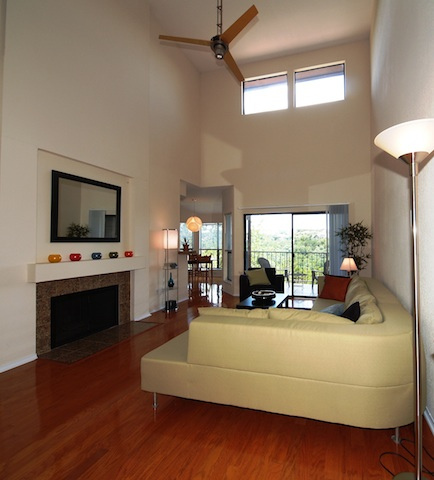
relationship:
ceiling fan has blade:
[158, 1, 259, 84] [222, 3, 258, 45]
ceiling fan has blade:
[158, 1, 259, 84] [158, 34, 214, 48]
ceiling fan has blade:
[158, 1, 259, 84] [223, 47, 246, 84]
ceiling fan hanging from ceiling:
[158, 1, 259, 84] [154, 1, 376, 74]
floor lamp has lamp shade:
[375, 115, 433, 479] [372, 116, 433, 169]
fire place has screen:
[35, 269, 131, 357] [52, 284, 120, 346]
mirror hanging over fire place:
[49, 166, 122, 245] [35, 269, 131, 357]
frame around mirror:
[50, 168, 122, 244] [49, 166, 122, 245]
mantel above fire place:
[26, 253, 145, 283] [35, 269, 131, 357]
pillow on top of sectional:
[318, 273, 351, 303] [139, 275, 427, 446]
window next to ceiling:
[292, 59, 347, 110] [154, 1, 376, 74]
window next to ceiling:
[236, 71, 288, 118] [154, 1, 376, 74]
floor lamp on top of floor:
[375, 115, 433, 479] [1, 296, 432, 479]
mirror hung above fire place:
[49, 166, 122, 245] [35, 269, 131, 357]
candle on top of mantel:
[48, 252, 62, 264] [26, 253, 145, 283]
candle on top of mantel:
[69, 253, 82, 262] [26, 253, 145, 283]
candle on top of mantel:
[91, 250, 103, 261] [26, 253, 145, 283]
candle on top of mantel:
[108, 250, 119, 259] [26, 253, 145, 283]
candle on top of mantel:
[123, 249, 134, 260] [26, 253, 145, 283]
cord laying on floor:
[378, 435, 433, 478] [1, 296, 432, 479]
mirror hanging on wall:
[49, 166, 122, 245] [0, 0, 149, 374]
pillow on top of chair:
[245, 267, 270, 287] [238, 265, 283, 303]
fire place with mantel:
[35, 269, 131, 357] [26, 253, 145, 283]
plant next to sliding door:
[336, 219, 373, 277] [243, 213, 328, 300]